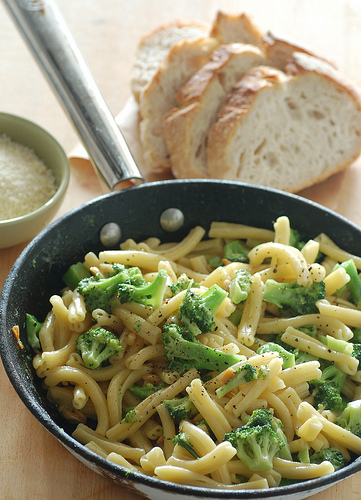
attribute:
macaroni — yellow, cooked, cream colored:
[32, 215, 361, 491]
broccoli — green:
[22, 231, 360, 472]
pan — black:
[4, 2, 361, 499]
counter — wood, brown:
[2, 152, 360, 496]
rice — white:
[1, 134, 60, 224]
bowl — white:
[2, 110, 72, 250]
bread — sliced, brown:
[122, 11, 360, 184]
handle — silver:
[6, 2, 145, 190]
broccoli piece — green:
[74, 326, 121, 371]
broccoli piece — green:
[227, 410, 287, 472]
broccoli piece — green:
[264, 278, 329, 317]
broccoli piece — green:
[75, 268, 143, 314]